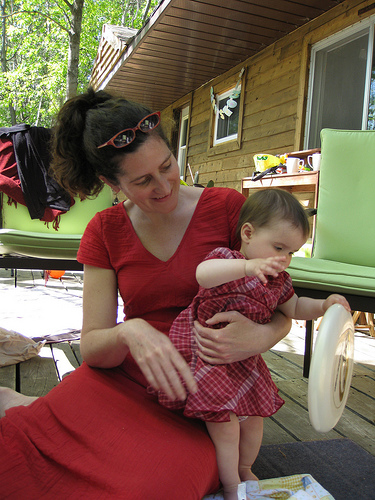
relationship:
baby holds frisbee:
[143, 187, 355, 499] [302, 302, 355, 435]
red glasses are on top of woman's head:
[93, 110, 165, 151] [83, 102, 184, 217]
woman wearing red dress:
[2, 90, 294, 499] [1, 185, 247, 499]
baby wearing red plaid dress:
[143, 187, 355, 499] [165, 245, 300, 425]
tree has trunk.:
[0, 1, 87, 124] [64, 1, 85, 99]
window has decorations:
[206, 67, 248, 156] [207, 67, 247, 121]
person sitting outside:
[2, 90, 294, 499] [1, 5, 372, 496]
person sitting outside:
[143, 187, 355, 499] [1, 5, 372, 496]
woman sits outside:
[2, 90, 294, 499] [1, 5, 372, 496]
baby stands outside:
[143, 187, 355, 499] [1, 5, 372, 496]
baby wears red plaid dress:
[143, 187, 355, 499] [165, 245, 300, 425]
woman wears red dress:
[2, 90, 294, 499] [1, 185, 247, 499]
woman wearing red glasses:
[2, 90, 294, 499] [93, 110, 165, 151]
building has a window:
[91, 2, 374, 261] [206, 67, 248, 156]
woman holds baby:
[2, 90, 294, 499] [143, 187, 355, 499]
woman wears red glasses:
[2, 90, 294, 499] [93, 110, 165, 151]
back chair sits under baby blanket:
[0, 127, 133, 292] [0, 131, 76, 231]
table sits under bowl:
[235, 147, 324, 260] [248, 151, 284, 180]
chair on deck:
[279, 126, 374, 382] [1, 267, 372, 499]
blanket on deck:
[236, 472, 336, 499] [1, 267, 372, 499]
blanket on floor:
[232, 467, 341, 499] [1, 267, 372, 499]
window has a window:
[298, 15, 374, 162] [300, 15, 373, 161]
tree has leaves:
[0, 1, 87, 124] [1, 2, 160, 130]